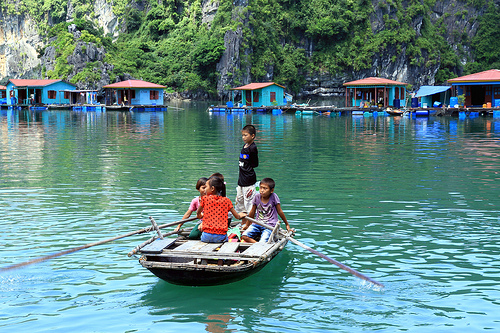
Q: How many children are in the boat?
A: 4.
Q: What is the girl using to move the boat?
A: An oar.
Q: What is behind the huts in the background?
A: A mountain.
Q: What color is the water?
A: Green.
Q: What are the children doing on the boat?
A: Playing.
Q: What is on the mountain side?
A: Vegetation.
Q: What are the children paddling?
A: Boat.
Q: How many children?
A: 4.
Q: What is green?
A: The water.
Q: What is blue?
A: The houses.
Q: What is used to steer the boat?
A: Oar.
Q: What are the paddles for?
A: Steering.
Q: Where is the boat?
A: In the water.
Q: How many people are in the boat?
A: Four.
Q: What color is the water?
A: Blue.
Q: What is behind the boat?
A: Blue huts.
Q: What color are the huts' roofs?
A: Red.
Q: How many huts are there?
A: Five.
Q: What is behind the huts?
A: A cliff.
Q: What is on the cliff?
A: Bushes.